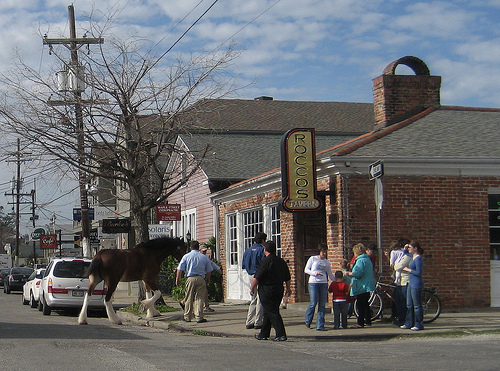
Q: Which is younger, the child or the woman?
A: The child is younger than the woman.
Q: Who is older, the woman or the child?
A: The woman is older than the child.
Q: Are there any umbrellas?
A: No, there are no umbrellas.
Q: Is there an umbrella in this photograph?
A: No, there are no umbrellas.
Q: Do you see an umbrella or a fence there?
A: No, there are no umbrellas or fences.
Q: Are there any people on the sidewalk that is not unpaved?
A: Yes, there are people on the sidewalk.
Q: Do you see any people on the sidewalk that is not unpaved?
A: Yes, there are people on the sidewalk.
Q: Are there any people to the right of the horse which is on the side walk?
A: Yes, there are people to the right of the horse.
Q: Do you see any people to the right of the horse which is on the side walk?
A: Yes, there are people to the right of the horse.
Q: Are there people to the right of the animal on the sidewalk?
A: Yes, there are people to the right of the horse.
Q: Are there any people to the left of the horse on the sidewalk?
A: No, the people are to the right of the horse.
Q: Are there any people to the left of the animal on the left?
A: No, the people are to the right of the horse.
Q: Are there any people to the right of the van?
A: Yes, there are people to the right of the van.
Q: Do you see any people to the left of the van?
A: No, the people are to the right of the van.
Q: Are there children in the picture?
A: Yes, there is a child.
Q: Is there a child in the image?
A: Yes, there is a child.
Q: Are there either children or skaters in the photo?
A: Yes, there is a child.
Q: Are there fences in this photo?
A: No, there are no fences.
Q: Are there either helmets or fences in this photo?
A: No, there are no fences or helmets.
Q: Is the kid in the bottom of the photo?
A: Yes, the kid is in the bottom of the image.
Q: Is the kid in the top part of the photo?
A: No, the kid is in the bottom of the image.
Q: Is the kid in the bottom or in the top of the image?
A: The kid is in the bottom of the image.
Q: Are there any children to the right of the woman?
A: Yes, there is a child to the right of the woman.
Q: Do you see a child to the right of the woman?
A: Yes, there is a child to the right of the woman.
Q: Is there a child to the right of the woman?
A: Yes, there is a child to the right of the woman.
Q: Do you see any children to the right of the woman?
A: Yes, there is a child to the right of the woman.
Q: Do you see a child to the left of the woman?
A: No, the child is to the right of the woman.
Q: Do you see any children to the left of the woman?
A: No, the child is to the right of the woman.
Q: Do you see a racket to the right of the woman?
A: No, there is a child to the right of the woman.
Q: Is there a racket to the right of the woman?
A: No, there is a child to the right of the woman.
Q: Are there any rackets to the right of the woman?
A: No, there is a child to the right of the woman.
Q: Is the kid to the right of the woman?
A: Yes, the kid is to the right of the woman.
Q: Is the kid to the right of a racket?
A: No, the kid is to the right of the woman.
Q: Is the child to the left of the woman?
A: No, the child is to the right of the woman.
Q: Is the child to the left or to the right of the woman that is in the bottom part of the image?
A: The child is to the right of the woman.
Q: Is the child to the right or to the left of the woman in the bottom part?
A: The child is to the right of the woman.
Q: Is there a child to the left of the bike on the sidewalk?
A: Yes, there is a child to the left of the bike.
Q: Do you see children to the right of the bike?
A: No, the child is to the left of the bike.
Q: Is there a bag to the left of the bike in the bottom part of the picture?
A: No, there is a child to the left of the bike.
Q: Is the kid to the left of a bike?
A: Yes, the kid is to the left of a bike.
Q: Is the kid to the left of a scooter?
A: No, the kid is to the left of a bike.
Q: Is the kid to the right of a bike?
A: No, the kid is to the left of a bike.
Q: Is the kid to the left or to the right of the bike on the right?
A: The kid is to the left of the bike.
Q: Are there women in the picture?
A: Yes, there is a woman.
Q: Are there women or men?
A: Yes, there is a woman.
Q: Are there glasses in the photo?
A: No, there are no glasses.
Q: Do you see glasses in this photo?
A: No, there are no glasses.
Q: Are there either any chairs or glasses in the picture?
A: No, there are no glasses or chairs.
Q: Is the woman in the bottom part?
A: Yes, the woman is in the bottom of the image.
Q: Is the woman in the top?
A: No, the woman is in the bottom of the image.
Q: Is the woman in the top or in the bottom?
A: The woman is in the bottom of the image.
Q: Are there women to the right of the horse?
A: Yes, there is a woman to the right of the horse.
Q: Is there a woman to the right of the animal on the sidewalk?
A: Yes, there is a woman to the right of the horse.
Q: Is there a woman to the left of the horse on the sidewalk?
A: No, the woman is to the right of the horse.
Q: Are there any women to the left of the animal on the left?
A: No, the woman is to the right of the horse.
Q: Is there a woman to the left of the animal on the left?
A: No, the woman is to the right of the horse.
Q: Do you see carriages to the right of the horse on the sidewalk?
A: No, there is a woman to the right of the horse.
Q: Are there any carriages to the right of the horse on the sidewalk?
A: No, there is a woman to the right of the horse.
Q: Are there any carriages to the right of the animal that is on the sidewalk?
A: No, there is a woman to the right of the horse.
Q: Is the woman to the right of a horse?
A: Yes, the woman is to the right of a horse.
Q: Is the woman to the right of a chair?
A: No, the woman is to the right of a horse.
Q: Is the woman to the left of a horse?
A: No, the woman is to the right of a horse.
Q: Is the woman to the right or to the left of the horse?
A: The woman is to the right of the horse.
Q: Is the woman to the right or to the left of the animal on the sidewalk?
A: The woman is to the right of the horse.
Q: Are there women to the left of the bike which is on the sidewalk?
A: Yes, there is a woman to the left of the bike.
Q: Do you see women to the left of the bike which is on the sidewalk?
A: Yes, there is a woman to the left of the bike.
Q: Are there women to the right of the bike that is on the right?
A: No, the woman is to the left of the bike.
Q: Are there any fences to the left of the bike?
A: No, there is a woman to the left of the bike.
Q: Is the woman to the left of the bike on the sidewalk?
A: Yes, the woman is to the left of the bike.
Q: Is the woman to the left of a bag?
A: No, the woman is to the left of the bike.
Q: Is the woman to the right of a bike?
A: No, the woman is to the left of a bike.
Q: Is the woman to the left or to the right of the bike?
A: The woman is to the left of the bike.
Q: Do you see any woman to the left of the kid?
A: Yes, there is a woman to the left of the kid.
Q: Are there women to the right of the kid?
A: No, the woman is to the left of the kid.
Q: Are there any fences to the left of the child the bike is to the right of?
A: No, there is a woman to the left of the child.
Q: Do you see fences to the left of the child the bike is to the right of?
A: No, there is a woman to the left of the child.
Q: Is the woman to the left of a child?
A: Yes, the woman is to the left of a child.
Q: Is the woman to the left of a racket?
A: No, the woman is to the left of a child.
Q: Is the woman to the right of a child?
A: No, the woman is to the left of a child.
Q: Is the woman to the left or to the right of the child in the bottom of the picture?
A: The woman is to the left of the child.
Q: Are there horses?
A: Yes, there is a horse.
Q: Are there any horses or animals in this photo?
A: Yes, there is a horse.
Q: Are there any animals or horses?
A: Yes, there is a horse.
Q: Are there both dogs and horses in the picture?
A: No, there is a horse but no dogs.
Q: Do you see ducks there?
A: No, there are no ducks.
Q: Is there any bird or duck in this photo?
A: No, there are no ducks or birds.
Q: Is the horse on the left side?
A: Yes, the horse is on the left of the image.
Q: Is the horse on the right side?
A: No, the horse is on the left of the image.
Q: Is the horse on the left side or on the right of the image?
A: The horse is on the left of the image.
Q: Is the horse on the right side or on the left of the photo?
A: The horse is on the left of the image.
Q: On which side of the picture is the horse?
A: The horse is on the left of the image.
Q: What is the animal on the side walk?
A: The animal is a horse.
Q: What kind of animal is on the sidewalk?
A: The animal is a horse.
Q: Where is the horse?
A: The horse is on the sidewalk.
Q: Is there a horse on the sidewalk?
A: Yes, there is a horse on the sidewalk.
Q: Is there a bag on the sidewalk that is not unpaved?
A: No, there is a horse on the side walk.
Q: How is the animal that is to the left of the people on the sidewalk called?
A: The animal is a horse.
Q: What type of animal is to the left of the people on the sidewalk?
A: The animal is a horse.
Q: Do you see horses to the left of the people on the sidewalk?
A: Yes, there is a horse to the left of the people.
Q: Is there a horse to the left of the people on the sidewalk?
A: Yes, there is a horse to the left of the people.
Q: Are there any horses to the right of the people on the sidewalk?
A: No, the horse is to the left of the people.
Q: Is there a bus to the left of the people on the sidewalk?
A: No, there is a horse to the left of the people.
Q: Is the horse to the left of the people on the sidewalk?
A: Yes, the horse is to the left of the people.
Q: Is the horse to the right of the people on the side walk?
A: No, the horse is to the left of the people.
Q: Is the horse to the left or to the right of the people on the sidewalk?
A: The horse is to the left of the people.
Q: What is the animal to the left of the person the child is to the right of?
A: The animal is a horse.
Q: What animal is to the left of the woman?
A: The animal is a horse.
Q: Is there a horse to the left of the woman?
A: Yes, there is a horse to the left of the woman.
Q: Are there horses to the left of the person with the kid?
A: Yes, there is a horse to the left of the woman.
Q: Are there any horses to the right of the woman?
A: No, the horse is to the left of the woman.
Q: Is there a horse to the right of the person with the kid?
A: No, the horse is to the left of the woman.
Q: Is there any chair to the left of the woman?
A: No, there is a horse to the left of the woman.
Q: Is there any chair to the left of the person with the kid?
A: No, there is a horse to the left of the woman.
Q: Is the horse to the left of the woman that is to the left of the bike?
A: Yes, the horse is to the left of the woman.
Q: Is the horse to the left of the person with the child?
A: Yes, the horse is to the left of the woman.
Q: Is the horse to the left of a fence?
A: No, the horse is to the left of the woman.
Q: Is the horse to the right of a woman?
A: No, the horse is to the left of a woman.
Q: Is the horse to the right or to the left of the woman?
A: The horse is to the left of the woman.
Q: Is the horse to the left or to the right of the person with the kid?
A: The horse is to the left of the woman.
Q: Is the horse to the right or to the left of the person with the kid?
A: The horse is to the left of the woman.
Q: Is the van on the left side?
A: Yes, the van is on the left of the image.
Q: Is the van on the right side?
A: No, the van is on the left of the image.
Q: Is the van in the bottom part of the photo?
A: Yes, the van is in the bottom of the image.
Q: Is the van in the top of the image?
A: No, the van is in the bottom of the image.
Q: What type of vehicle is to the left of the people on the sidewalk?
A: The vehicle is a van.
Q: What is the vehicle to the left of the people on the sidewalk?
A: The vehicle is a van.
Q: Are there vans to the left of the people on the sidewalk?
A: Yes, there is a van to the left of the people.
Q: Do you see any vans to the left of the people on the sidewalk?
A: Yes, there is a van to the left of the people.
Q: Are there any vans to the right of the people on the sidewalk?
A: No, the van is to the left of the people.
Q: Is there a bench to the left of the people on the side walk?
A: No, there is a van to the left of the people.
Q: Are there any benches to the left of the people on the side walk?
A: No, there is a van to the left of the people.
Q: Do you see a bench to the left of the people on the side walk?
A: No, there is a van to the left of the people.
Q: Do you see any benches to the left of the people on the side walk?
A: No, there is a van to the left of the people.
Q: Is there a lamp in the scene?
A: No, there are no lamps.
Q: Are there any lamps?
A: No, there are no lamps.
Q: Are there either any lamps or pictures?
A: No, there are no lamps or pictures.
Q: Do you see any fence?
A: No, there are no fences.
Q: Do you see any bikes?
A: Yes, there is a bike.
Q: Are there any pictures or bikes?
A: Yes, there is a bike.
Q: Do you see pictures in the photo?
A: No, there are no pictures.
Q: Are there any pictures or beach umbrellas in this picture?
A: No, there are no pictures or beach umbrellas.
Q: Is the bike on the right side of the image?
A: Yes, the bike is on the right of the image.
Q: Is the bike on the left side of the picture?
A: No, the bike is on the right of the image.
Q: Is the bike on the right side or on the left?
A: The bike is on the right of the image.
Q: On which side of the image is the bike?
A: The bike is on the right of the image.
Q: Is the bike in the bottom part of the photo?
A: Yes, the bike is in the bottom of the image.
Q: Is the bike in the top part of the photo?
A: No, the bike is in the bottom of the image.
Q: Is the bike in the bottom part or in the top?
A: The bike is in the bottom of the image.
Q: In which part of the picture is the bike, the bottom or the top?
A: The bike is in the bottom of the image.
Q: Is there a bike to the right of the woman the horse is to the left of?
A: Yes, there is a bike to the right of the woman.